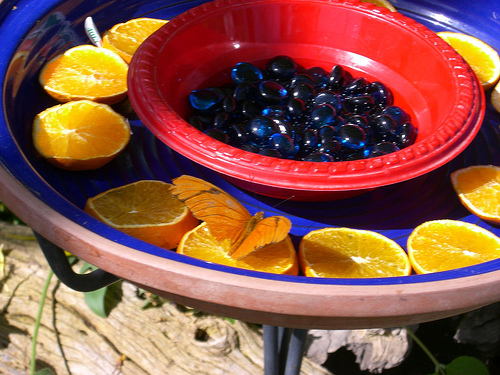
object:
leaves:
[395, 325, 493, 375]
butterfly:
[165, 174, 293, 259]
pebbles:
[189, 86, 224, 111]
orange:
[96, 15, 170, 65]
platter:
[1, 3, 498, 323]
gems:
[337, 124, 368, 150]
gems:
[375, 114, 395, 134]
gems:
[348, 97, 368, 109]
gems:
[317, 125, 335, 145]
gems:
[285, 99, 304, 115]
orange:
[176, 220, 302, 283]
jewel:
[370, 81, 391, 105]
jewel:
[310, 104, 335, 125]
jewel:
[335, 123, 367, 149]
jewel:
[250, 116, 280, 139]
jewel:
[382, 105, 408, 120]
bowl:
[126, 0, 486, 201]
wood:
[0, 220, 333, 375]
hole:
[194, 329, 211, 341]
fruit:
[41, 45, 128, 101]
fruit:
[34, 100, 133, 166]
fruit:
[85, 177, 195, 247]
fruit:
[300, 227, 410, 278]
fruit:
[407, 217, 500, 276]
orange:
[448, 161, 498, 221]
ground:
[0, 197, 498, 375]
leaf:
[82, 266, 116, 318]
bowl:
[0, 1, 498, 329]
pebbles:
[231, 62, 263, 84]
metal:
[242, 310, 314, 375]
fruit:
[298, 225, 411, 288]